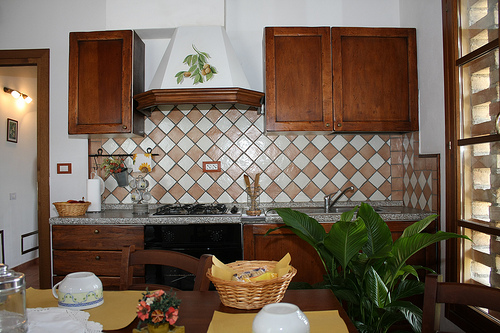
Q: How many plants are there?
A: One.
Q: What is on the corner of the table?
A: Basket.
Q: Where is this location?
A: Kitchen.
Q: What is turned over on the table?
A: Mugs.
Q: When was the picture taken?
A: Daytime.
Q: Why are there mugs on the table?
A: For drinks.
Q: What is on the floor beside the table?
A: Plant.